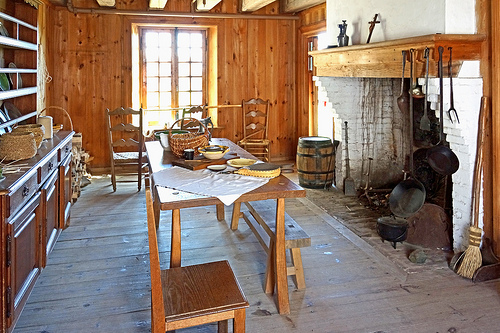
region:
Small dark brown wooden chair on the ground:
[125, 194, 277, 331]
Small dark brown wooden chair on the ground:
[236, 90, 288, 162]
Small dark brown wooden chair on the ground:
[96, 97, 140, 189]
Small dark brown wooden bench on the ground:
[228, 194, 320, 296]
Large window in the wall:
[121, 18, 233, 126]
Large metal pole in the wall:
[63, 2, 303, 32]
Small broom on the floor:
[456, 87, 484, 280]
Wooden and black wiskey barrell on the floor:
[288, 113, 338, 198]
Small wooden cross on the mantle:
[356, 15, 393, 61]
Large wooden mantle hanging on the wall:
[301, 33, 482, 93]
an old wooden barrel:
[293, 136, 338, 191]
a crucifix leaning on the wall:
[366, 13, 380, 45]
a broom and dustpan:
[451, 94, 497, 284]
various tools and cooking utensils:
[387, 44, 462, 220]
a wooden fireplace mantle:
[309, 33, 490, 83]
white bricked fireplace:
[311, 75, 497, 260]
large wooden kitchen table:
[139, 136, 306, 316]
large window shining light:
[132, 22, 219, 126]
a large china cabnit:
[0, 0, 80, 330]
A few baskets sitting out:
[0, 117, 213, 160]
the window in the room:
[138, 26, 208, 126]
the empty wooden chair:
[142, 188, 248, 330]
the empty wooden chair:
[105, 107, 151, 189]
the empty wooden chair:
[238, 96, 271, 167]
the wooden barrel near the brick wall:
[295, 133, 337, 188]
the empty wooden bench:
[231, 198, 309, 293]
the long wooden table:
[138, 133, 304, 320]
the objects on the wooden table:
[142, 115, 279, 205]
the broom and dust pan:
[448, 97, 498, 281]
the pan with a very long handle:
[388, 47, 425, 217]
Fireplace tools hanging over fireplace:
[311, 43, 463, 265]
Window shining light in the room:
[132, 22, 218, 127]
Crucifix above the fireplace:
[361, 12, 383, 45]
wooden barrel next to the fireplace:
[296, 134, 341, 187]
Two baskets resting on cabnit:
[1, 125, 46, 163]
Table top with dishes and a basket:
[144, 113, 307, 217]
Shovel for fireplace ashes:
[340, 118, 359, 198]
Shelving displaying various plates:
[2, 5, 35, 135]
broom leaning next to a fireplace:
[451, 96, 498, 279]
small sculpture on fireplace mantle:
[326, 18, 354, 48]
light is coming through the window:
[125, 18, 221, 123]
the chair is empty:
[102, 180, 260, 324]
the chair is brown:
[111, 187, 267, 324]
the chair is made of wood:
[108, 185, 267, 322]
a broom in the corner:
[454, 76, 490, 289]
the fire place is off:
[317, 60, 461, 232]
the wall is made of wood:
[207, 17, 294, 152]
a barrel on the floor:
[278, 110, 338, 190]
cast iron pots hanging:
[358, 84, 450, 256]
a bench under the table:
[220, 197, 317, 279]